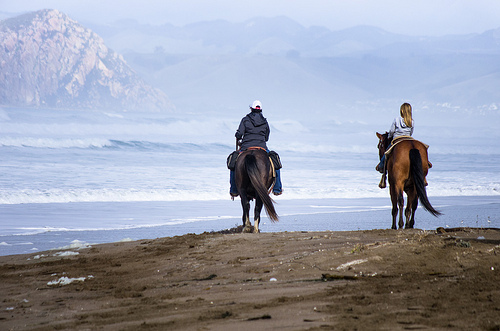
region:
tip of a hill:
[41, 5, 67, 12]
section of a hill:
[88, 69, 114, 91]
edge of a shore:
[210, 240, 295, 291]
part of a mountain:
[55, 35, 71, 55]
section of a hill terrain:
[292, 33, 320, 55]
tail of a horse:
[253, 161, 256, 176]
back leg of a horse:
[396, 190, 412, 218]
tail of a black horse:
[410, 175, 423, 195]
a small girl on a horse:
[383, 106, 409, 148]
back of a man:
[245, 115, 262, 132]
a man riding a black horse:
[218, 96, 289, 238]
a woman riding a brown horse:
[369, 97, 444, 233]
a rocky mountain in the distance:
[4, 6, 180, 119]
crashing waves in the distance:
[2, 106, 497, 201]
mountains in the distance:
[0, 1, 497, 130]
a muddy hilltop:
[9, 225, 497, 326]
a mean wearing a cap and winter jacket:
[232, 98, 271, 150]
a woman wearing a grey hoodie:
[382, 99, 415, 141]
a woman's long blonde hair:
[397, 100, 414, 128]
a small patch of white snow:
[45, 265, 92, 287]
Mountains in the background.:
[0, 2, 167, 118]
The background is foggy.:
[5, 0, 499, 107]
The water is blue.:
[8, 132, 489, 212]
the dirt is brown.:
[19, 214, 492, 321]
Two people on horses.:
[213, 78, 454, 238]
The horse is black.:
[223, 142, 284, 237]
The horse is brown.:
[366, 117, 436, 227]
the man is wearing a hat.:
[244, 96, 266, 113]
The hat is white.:
[243, 95, 266, 115]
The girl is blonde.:
[395, 100, 416, 130]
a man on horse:
[202, 68, 309, 256]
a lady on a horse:
[367, 57, 467, 270]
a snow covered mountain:
[0, 0, 183, 145]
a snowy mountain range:
[124, 0, 496, 87]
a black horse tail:
[396, 130, 461, 235]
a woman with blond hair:
[364, 79, 448, 222]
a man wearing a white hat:
[194, 74, 313, 261]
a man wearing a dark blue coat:
[197, 80, 327, 253]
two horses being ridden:
[209, 66, 494, 286]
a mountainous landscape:
[16, 3, 492, 231]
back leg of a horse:
[397, 187, 406, 202]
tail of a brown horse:
[418, 187, 423, 200]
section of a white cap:
[252, 105, 259, 110]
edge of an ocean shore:
[107, 237, 124, 257]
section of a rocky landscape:
[373, 265, 393, 292]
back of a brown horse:
[396, 158, 409, 171]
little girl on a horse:
[398, 107, 411, 132]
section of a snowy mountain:
[81, 47, 101, 74]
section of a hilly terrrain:
[107, 55, 132, 91]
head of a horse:
[381, 131, 387, 143]